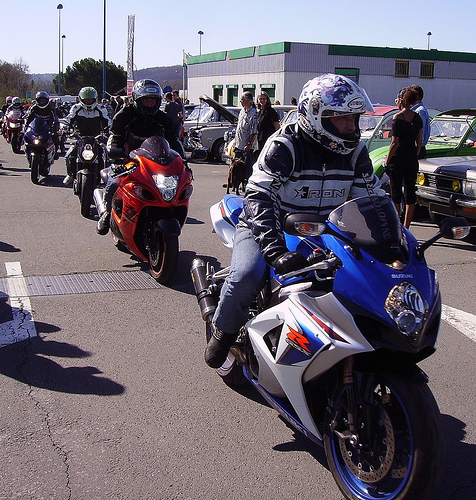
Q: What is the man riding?
A: Motorcycle.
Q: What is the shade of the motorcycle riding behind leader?
A: Red.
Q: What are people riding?
A: Motorbikes.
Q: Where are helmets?
A: On rider's heads.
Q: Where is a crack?
A: On the pavement.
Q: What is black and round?
A: Tires.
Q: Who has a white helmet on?
A: Rider in the front.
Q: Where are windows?
A: On a building.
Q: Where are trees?
A: In the distance.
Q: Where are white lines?
A: On the ground.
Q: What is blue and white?
A: Motorbike in the front.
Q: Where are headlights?
A: On the front of the motorbikes.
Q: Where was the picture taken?
A: On a street.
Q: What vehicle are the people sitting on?
A: Motorcycles.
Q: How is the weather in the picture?
A: Sunny.